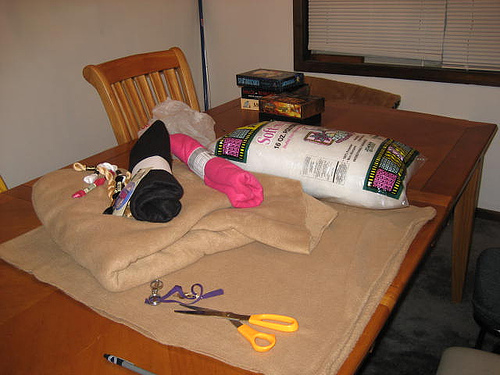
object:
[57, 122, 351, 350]
fleece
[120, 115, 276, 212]
fabric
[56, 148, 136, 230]
threads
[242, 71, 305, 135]
boxes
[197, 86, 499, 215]
table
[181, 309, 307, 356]
scissors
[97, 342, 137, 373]
pen